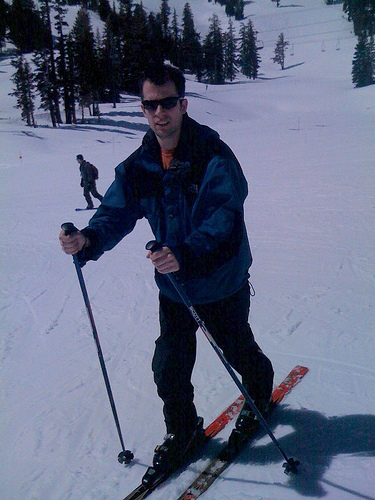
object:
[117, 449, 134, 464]
end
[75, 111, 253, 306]
jacket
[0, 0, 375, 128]
evergreen trees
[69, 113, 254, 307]
suit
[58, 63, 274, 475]
he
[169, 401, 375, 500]
shadow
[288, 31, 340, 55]
lift chairs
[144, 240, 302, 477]
poles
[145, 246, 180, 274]
hand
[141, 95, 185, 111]
eyeglass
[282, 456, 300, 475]
grip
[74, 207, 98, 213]
snowboard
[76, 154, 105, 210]
man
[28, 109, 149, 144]
shadow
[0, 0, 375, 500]
snow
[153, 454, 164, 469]
black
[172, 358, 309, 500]
ski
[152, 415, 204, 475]
shoe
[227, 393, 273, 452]
shoe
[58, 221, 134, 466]
pole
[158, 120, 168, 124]
teeth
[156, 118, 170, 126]
mouth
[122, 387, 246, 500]
ski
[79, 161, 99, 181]
back pack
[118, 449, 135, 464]
disk grip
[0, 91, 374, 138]
air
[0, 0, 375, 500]
ground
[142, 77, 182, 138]
face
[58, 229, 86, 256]
hand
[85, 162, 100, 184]
back